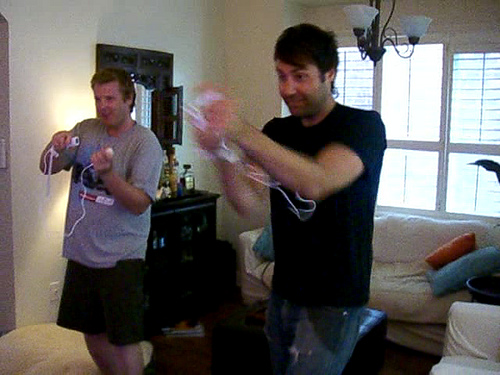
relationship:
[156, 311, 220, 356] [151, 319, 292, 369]
books on floor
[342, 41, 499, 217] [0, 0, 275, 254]
window on wall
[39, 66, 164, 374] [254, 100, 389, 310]
boy in black shirt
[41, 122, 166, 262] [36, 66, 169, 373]
shirt on man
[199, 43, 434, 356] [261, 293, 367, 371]
boy has blue pants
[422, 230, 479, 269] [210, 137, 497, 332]
pillow on couch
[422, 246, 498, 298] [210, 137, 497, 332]
pillow on couch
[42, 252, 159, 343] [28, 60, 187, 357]
shorts on man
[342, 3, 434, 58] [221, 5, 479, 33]
light hanging from ceiling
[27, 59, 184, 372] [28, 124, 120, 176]
boy holds controllers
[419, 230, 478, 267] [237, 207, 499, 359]
pillow on sofa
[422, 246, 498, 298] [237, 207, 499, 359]
pillow on sofa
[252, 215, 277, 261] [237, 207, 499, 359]
pillow on sofa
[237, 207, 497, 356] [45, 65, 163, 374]
sofa behind boy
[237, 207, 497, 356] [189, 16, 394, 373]
sofa behind boy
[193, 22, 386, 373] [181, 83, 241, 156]
boy holding game controller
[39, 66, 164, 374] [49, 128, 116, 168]
boy holding game controller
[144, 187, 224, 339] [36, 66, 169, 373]
chest behind man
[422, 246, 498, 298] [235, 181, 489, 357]
pillow on sofa